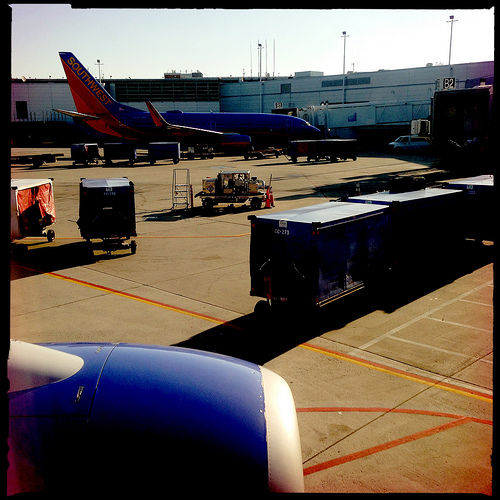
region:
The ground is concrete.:
[325, 349, 485, 490]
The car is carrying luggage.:
[246, 173, 489, 323]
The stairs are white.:
[158, 157, 204, 210]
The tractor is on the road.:
[186, 152, 275, 215]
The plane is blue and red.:
[54, 39, 344, 172]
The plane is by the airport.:
[48, 52, 369, 180]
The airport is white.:
[195, 59, 492, 139]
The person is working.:
[248, 176, 287, 210]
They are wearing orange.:
[255, 179, 287, 218]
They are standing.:
[247, 171, 289, 228]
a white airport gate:
[272, 85, 432, 139]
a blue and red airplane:
[52, 50, 322, 155]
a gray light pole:
[336, 27, 356, 107]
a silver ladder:
[167, 163, 194, 216]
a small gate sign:
[440, 77, 458, 89]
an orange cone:
[268, 185, 274, 211]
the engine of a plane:
[6, 338, 313, 494]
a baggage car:
[242, 197, 400, 321]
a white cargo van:
[382, 131, 429, 154]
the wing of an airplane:
[144, 97, 239, 149]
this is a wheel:
[38, 222, 58, 252]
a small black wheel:
[128, 229, 139, 259]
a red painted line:
[309, 322, 476, 442]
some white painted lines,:
[402, 296, 471, 368]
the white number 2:
[279, 225, 286, 236]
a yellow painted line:
[57, 272, 188, 343]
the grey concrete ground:
[304, 361, 341, 394]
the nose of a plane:
[0, 293, 327, 487]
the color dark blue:
[185, 387, 198, 400]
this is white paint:
[268, 430, 287, 462]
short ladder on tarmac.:
[172, 167, 192, 214]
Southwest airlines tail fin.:
[57, 49, 143, 115]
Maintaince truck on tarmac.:
[195, 168, 271, 212]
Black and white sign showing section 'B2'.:
[442, 77, 453, 89]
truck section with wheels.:
[147, 143, 179, 164]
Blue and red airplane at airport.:
[50, 52, 320, 152]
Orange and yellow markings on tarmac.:
[334, 340, 486, 475]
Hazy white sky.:
[117, 20, 233, 60]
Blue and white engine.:
[3, 342, 306, 497]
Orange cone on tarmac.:
[261, 186, 274, 208]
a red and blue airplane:
[49, 50, 321, 157]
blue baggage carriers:
[246, 169, 498, 312]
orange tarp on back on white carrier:
[14, 180, 54, 240]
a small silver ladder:
[170, 166, 194, 216]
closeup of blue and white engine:
[6, 336, 304, 498]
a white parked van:
[387, 134, 430, 154]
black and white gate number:
[441, 76, 456, 91]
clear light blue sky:
[10, 6, 494, 78]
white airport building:
[8, 61, 493, 136]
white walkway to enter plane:
[296, 94, 431, 129]